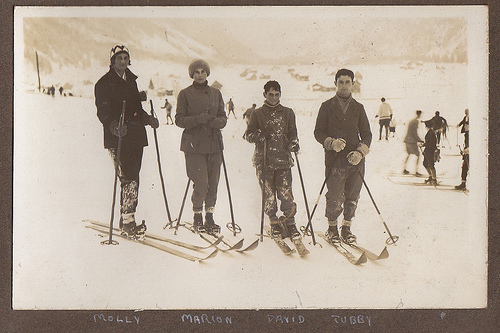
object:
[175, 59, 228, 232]
woman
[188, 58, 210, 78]
hat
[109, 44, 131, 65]
hat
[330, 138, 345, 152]
gloves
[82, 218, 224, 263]
skiis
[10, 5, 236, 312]
left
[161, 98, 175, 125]
person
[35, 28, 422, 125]
distance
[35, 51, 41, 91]
post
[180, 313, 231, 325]
names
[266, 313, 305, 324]
names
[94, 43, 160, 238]
person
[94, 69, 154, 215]
skii gear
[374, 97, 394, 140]
person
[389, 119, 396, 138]
toddler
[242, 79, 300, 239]
person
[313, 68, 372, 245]
kid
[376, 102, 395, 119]
top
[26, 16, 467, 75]
mountain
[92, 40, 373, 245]
family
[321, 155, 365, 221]
pants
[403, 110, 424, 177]
woman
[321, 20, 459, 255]
right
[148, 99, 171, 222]
skii pole